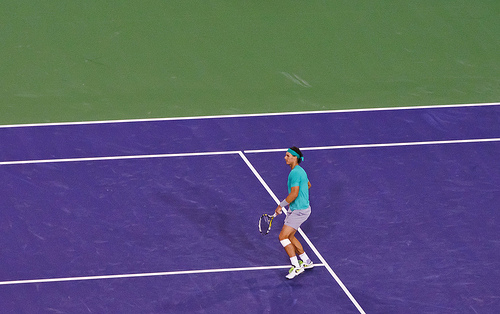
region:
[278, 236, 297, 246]
a white leg band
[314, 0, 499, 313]
part of a tennis court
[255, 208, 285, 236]
a large tennis racket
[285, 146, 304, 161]
a green headband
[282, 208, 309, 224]
a man's shorts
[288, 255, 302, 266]
a white sock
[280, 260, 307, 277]
a man's white tennis shoe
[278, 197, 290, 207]
a gray wristband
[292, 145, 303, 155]
part of a man's black hair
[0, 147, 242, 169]
a long white line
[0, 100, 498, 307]
purple tennis court with white lines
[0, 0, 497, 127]
green out of bounds on tennis court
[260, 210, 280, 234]
a tennis racket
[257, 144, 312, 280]
a professional tennis player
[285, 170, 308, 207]
the tennis player's blue shirt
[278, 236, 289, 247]
the white brace on his knee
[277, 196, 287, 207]
a gray wristband on his arm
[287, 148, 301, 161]
a blue headband on his head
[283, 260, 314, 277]
the tennis player's white shoes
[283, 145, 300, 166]
the tennis player's head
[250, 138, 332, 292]
man on a tennis court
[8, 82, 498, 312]
lines on the court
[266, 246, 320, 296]
sneakers on the man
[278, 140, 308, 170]
sweat band on the man's head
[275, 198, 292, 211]
wrist band on the hand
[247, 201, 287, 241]
racquet in the hand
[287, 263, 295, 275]
lace's on the shoe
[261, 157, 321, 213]
shirt on the player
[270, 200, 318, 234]
short's on the player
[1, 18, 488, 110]
area out of court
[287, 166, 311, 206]
The blue shirt the player is wearing.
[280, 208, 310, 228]
The gray shorts the player is wearing.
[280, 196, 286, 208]
The sweatband the player is wearing.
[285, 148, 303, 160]
The headband the player is wearing.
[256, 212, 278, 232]
The tennis racquet.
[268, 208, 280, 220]
The handle of the tennis racquet.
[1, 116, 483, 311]
The white boundary lines on the court.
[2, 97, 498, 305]
The blue area of the court.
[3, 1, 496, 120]
The green area of the court.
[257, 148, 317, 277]
tennis player getting ready for a return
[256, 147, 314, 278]
tennis player getting ready for a shot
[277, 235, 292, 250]
bandage or pad on the left leg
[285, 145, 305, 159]
a turquoise sweat band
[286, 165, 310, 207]
a turquoise t-shirt on the player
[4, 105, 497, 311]
blue tennis court area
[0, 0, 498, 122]
green out of bounds for doubles court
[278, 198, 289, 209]
white sweat band on the wrist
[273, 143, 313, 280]
man playing tennis under lights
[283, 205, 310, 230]
gray or light blue shorts